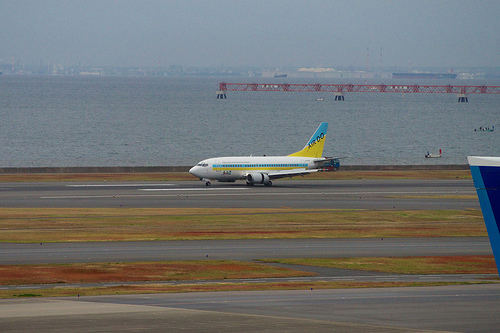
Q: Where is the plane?
A: On a runway.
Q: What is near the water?
A: A white airplane with yellow and blue stripes.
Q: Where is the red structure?
A: Over the water.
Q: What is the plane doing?
A: The plane is about to take off.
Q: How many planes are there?
A: One.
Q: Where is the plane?
A: On the runway.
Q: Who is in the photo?
A: Nobody.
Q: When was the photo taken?
A: Daytime.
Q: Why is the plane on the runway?
A: It's taxiing.